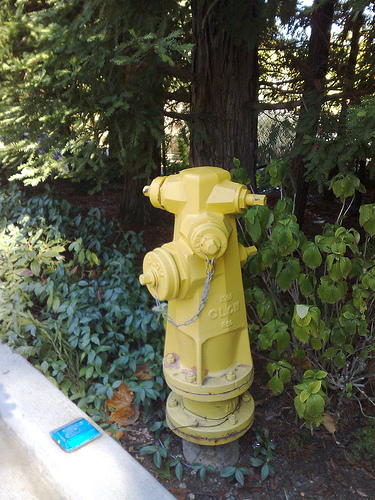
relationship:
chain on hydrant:
[143, 255, 216, 333] [137, 154, 271, 454]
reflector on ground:
[46, 412, 101, 459] [1, 140, 372, 499]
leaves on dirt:
[4, 194, 287, 492] [111, 320, 373, 500]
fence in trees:
[152, 103, 306, 209] [176, 1, 284, 222]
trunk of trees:
[185, 5, 273, 216] [176, 1, 284, 222]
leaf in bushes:
[292, 302, 312, 322] [237, 159, 373, 448]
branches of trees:
[247, 76, 374, 113] [176, 1, 284, 222]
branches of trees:
[111, 93, 198, 131] [176, 1, 284, 222]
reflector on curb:
[46, 412, 101, 459] [2, 340, 182, 499]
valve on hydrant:
[203, 238, 222, 259] [137, 154, 271, 454]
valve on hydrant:
[244, 192, 269, 213] [137, 154, 271, 454]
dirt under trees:
[111, 320, 373, 500] [176, 1, 284, 222]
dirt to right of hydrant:
[111, 320, 373, 500] [137, 154, 271, 454]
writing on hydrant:
[207, 290, 245, 336] [137, 154, 271, 454]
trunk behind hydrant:
[185, 5, 273, 216] [137, 154, 271, 454]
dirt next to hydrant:
[111, 320, 373, 500] [137, 154, 271, 454]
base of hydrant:
[174, 436, 245, 479] [137, 154, 271, 454]